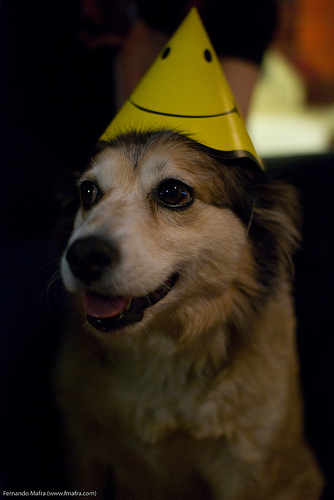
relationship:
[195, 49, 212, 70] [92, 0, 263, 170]
spot on hat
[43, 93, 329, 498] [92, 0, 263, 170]
dog has hat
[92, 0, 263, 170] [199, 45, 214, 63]
hat with spot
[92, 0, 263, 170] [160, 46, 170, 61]
hat with eye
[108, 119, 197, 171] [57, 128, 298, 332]
fur on head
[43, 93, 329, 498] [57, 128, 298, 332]
dog has head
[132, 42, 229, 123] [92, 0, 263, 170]
face on hat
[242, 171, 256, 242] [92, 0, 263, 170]
band attached to hat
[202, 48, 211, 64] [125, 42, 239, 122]
spot of face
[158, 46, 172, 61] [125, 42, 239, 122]
eye of face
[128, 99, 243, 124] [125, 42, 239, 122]
mouth of face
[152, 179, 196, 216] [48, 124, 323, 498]
eye of dog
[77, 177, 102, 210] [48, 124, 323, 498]
eye of dog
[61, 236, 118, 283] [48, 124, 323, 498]
nose of dog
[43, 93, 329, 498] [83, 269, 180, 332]
dog has open mouth